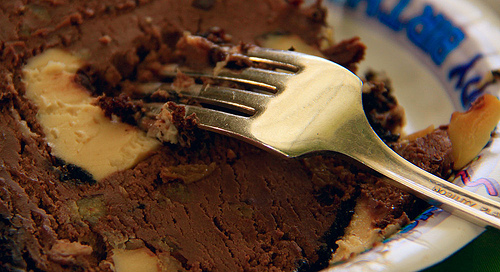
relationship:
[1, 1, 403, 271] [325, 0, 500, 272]
ice cream in bowl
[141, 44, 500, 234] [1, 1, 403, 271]
fork in ice cream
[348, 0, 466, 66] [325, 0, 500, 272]
writing on bowl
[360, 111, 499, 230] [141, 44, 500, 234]
handle on fork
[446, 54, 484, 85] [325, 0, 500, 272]
y on bowl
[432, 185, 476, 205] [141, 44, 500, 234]
writing on fork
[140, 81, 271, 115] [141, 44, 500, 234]
tine on fork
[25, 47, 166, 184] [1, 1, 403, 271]
vanilla in ice cream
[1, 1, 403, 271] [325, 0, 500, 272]
ice cream on bowl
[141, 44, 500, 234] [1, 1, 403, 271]
fork on ice cream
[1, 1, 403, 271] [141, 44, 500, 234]
ice cream on fork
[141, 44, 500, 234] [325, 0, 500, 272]
fork in bowl